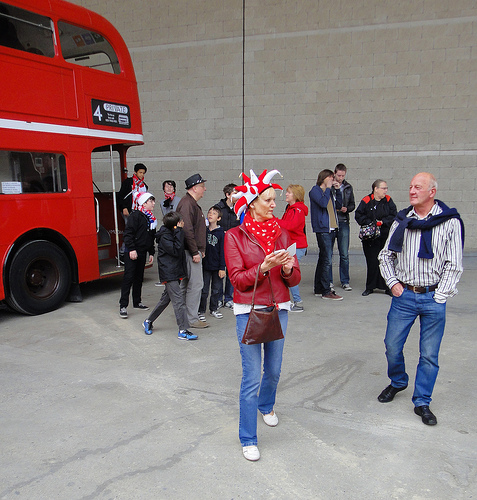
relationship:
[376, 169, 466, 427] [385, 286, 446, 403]
man in jeans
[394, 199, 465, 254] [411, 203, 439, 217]
sweater around neck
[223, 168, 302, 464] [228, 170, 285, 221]
lady wearing hat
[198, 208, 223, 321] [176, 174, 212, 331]
kid looking at grandpa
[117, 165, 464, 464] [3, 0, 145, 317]
crowd leaving bus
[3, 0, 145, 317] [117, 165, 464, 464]
bus dropped of crowd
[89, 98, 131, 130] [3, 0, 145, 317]
signage on side of bus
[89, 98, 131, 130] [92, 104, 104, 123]
signage designates number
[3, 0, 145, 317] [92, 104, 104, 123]
bus has number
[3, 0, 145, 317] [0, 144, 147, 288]
bus has deck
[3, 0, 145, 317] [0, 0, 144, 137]
bus has deck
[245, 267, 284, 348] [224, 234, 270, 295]
purse on arm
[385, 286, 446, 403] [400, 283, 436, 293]
jeans with belt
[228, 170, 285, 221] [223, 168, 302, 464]
hat on top of woman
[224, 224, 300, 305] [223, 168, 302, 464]
jacket worn on lady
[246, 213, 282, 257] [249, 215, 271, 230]
scarf on neck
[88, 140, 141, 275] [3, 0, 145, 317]
door in bus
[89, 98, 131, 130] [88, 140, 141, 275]
signage over door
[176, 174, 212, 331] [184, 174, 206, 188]
man in hat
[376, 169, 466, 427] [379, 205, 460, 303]
man in shirt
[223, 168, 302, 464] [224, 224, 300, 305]
lady wearing jacket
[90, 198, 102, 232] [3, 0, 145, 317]
railing on side of bus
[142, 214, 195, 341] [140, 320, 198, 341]
boy wearing shoes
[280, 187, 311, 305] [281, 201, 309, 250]
lady wearing sweatshirt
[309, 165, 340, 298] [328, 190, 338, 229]
guy wears scarf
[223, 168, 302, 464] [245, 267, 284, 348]
lady carrying purse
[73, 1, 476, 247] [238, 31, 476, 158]
wall has tiles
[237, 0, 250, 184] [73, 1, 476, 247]
lines in wall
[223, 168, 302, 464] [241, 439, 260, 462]
woman has foot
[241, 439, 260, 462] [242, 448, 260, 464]
foot has sneaker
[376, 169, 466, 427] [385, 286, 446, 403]
man wearing jeans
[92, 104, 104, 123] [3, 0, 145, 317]
number on bus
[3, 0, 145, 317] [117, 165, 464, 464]
bus holds passengers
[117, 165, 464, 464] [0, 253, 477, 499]
crowd on sidewalk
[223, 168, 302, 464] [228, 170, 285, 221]
woman wears hat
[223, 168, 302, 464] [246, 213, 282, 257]
woman wears scarf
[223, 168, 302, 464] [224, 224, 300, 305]
woman wears jacket